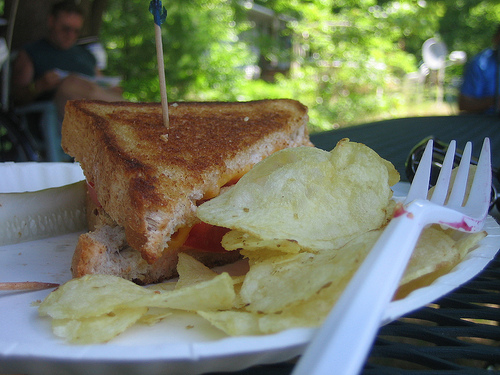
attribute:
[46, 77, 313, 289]
sandwich — toasted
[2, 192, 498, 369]
plate — paper, white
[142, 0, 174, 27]
frill — blue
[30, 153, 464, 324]
potato chips — yellow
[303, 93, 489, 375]
fork — plastic, white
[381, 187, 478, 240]
food — red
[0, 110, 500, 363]
table — iron, weaved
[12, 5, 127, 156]
man — reading, sitting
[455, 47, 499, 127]
shirt — blue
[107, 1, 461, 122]
foliage — green, big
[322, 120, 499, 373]
design — weaved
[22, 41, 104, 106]
shirt — green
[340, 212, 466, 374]
grate — metal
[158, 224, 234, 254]
sauce — red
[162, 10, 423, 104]
these — trees